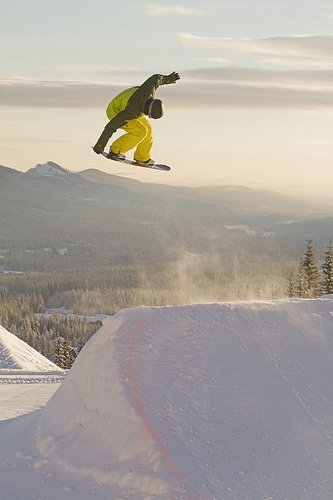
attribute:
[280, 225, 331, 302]
pine trees — tall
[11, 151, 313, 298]
mountains — covered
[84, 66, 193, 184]
snowboarder — flying, doing trick, snowboarding, airborn, wearing, jumping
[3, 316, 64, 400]
slope — steep, snow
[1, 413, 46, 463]
snow — white, covering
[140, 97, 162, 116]
hat — brown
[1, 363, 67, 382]
line — orange, red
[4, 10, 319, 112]
sky — bright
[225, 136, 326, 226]
fog — coming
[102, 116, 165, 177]
pants — yellow, light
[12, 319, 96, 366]
trees — green